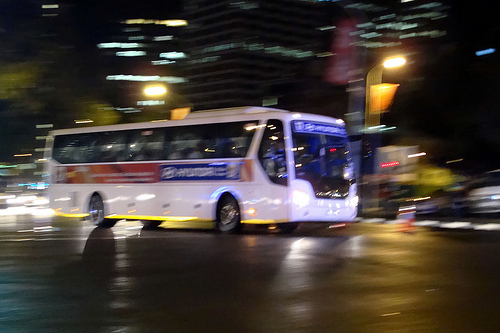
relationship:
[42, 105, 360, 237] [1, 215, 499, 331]
bus on street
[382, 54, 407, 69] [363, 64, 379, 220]
street light on a pole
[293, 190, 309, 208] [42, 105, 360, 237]
front light on bus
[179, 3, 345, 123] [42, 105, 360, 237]
building behind bus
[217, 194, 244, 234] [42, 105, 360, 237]
wheel on bus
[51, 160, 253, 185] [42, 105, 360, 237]
advertisement on bus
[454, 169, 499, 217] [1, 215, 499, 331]
car on street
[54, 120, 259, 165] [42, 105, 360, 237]
windows on bus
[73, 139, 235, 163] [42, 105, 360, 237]
passengers are seated on bus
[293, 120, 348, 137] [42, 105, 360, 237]
marquee on bus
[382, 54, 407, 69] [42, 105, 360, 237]
street light above bus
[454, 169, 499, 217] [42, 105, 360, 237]
car across from bus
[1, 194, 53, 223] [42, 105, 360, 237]
traffic behind bus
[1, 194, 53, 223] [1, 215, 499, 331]
traffic on street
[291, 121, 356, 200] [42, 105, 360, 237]
windshield on bus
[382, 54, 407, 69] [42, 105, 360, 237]
street light next to bus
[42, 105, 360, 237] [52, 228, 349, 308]
bus has shadow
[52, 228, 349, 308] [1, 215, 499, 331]
shadow on street